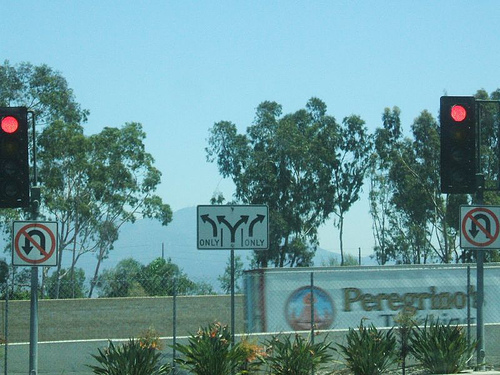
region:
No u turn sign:
[11, 215, 66, 270]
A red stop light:
[0, 102, 37, 209]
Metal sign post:
[26, 267, 42, 372]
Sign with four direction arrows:
[191, 203, 282, 251]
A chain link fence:
[6, 264, 499, 364]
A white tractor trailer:
[240, 260, 498, 337]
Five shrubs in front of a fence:
[85, 322, 499, 373]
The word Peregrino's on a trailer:
[331, 275, 491, 313]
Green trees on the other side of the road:
[54, 95, 186, 295]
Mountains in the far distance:
[118, 197, 198, 282]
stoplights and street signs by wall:
[10, 11, 499, 363]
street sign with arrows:
[151, 165, 311, 277]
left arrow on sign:
[191, 210, 219, 254]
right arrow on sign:
[243, 202, 268, 249]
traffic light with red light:
[0, 103, 36, 175]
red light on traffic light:
[406, 79, 481, 215]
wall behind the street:
[6, 285, 226, 349]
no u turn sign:
[1, 218, 58, 270]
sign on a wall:
[172, 265, 463, 352]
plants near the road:
[198, 327, 403, 359]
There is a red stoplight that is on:
[439, 100, 486, 167]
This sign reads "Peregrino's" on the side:
[345, 277, 487, 321]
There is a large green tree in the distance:
[254, 110, 323, 253]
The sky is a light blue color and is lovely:
[142, 87, 182, 130]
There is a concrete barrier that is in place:
[96, 304, 120, 331]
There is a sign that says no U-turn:
[461, 212, 498, 271]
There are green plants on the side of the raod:
[353, 327, 380, 354]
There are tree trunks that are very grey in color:
[70, 253, 82, 310]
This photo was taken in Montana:
[49, 93, 451, 371]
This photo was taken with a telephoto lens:
[80, 100, 442, 340]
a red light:
[442, 96, 477, 134]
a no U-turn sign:
[6, 221, 66, 272]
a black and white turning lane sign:
[187, 198, 287, 261]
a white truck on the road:
[242, 252, 498, 333]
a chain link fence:
[12, 270, 483, 373]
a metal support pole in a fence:
[164, 273, 181, 369]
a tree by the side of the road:
[70, 114, 170, 312]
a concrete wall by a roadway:
[0, 287, 243, 344]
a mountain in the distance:
[65, 202, 243, 299]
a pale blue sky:
[4, 4, 497, 253]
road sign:
[180, 197, 320, 282]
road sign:
[213, 180, 308, 261]